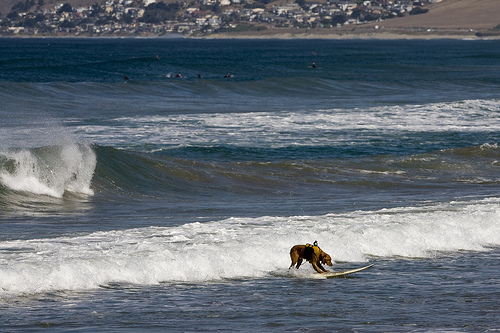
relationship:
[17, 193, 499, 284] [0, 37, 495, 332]
ripples in water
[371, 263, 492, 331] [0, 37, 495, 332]
ripples in water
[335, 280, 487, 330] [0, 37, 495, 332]
ripples in water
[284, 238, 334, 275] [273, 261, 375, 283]
dog on a surfboard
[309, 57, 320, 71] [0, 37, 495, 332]
surfer in water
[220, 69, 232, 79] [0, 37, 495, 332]
surfer in water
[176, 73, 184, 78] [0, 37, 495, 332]
people in water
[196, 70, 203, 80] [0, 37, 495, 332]
surfer in water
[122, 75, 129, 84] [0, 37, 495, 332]
people in water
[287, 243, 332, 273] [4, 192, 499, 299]
dog on wave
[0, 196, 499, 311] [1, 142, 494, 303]
foam on wave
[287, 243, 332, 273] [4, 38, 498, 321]
dog in ocean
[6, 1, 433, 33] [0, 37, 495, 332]
rocks across water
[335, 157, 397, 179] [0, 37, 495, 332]
ripples in water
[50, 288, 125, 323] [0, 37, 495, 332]
ripples in water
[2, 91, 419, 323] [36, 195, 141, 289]
ripples in water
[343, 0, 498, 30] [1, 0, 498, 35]
land in distance